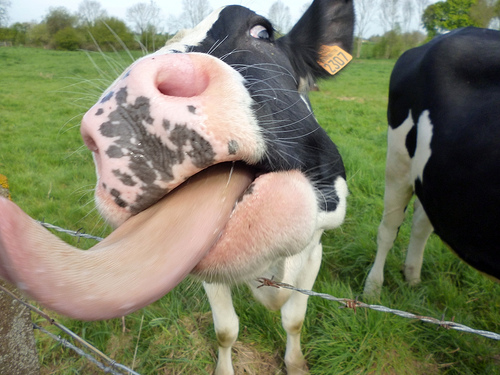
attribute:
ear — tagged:
[294, 5, 358, 84]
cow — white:
[78, 19, 411, 361]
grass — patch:
[14, 79, 53, 151]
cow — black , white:
[362, 24, 497, 304]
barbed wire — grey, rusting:
[255, 275, 497, 340]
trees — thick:
[31, 15, 139, 60]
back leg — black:
[350, 120, 412, 307]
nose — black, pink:
[74, 55, 232, 172]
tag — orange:
[312, 43, 358, 76]